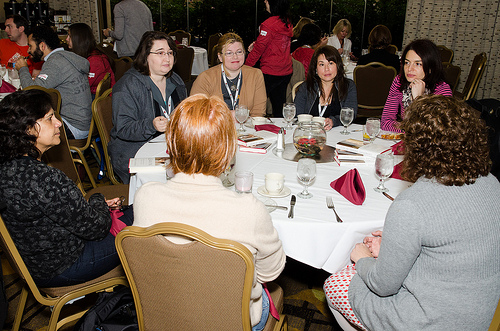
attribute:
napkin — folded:
[328, 170, 367, 206]